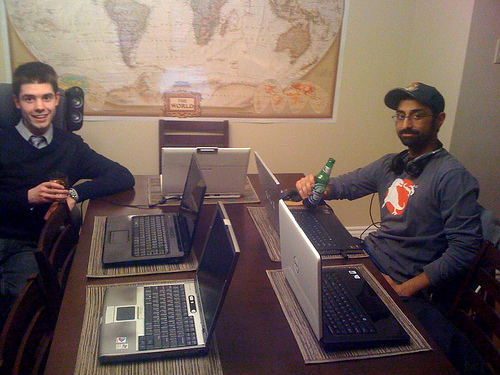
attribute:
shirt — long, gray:
[326, 150, 484, 287]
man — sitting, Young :
[295, 78, 486, 297]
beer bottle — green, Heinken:
[301, 154, 338, 213]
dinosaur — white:
[379, 177, 418, 221]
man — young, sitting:
[1, 60, 135, 321]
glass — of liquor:
[48, 166, 70, 195]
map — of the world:
[2, 0, 352, 123]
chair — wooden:
[157, 119, 230, 176]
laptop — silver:
[159, 140, 246, 199]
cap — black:
[377, 77, 453, 124]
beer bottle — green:
[290, 142, 369, 221]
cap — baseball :
[378, 68, 449, 112]